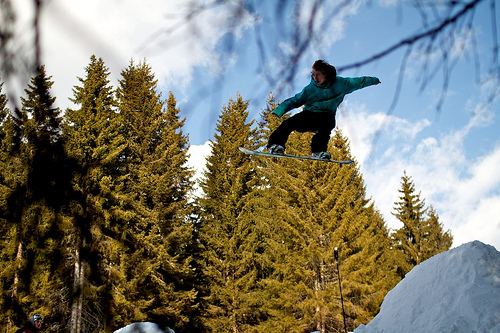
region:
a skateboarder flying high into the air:
[13, 8, 463, 313]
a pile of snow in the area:
[335, 226, 495, 322]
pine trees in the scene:
[5, 40, 171, 325]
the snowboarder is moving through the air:
[267, 65, 383, 115]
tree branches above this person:
[192, 10, 472, 45]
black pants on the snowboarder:
[260, 120, 345, 145]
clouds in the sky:
[371, 115, 491, 210]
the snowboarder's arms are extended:
[265, 55, 395, 115]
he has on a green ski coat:
[260, 79, 371, 119]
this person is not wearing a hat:
[302, 58, 345, 89]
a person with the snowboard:
[228, 51, 388, 169]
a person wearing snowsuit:
[281, 67, 353, 162]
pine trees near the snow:
[221, 93, 383, 323]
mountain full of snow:
[417, 246, 499, 330]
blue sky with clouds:
[396, 102, 487, 192]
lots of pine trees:
[23, 70, 365, 302]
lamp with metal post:
[329, 243, 360, 329]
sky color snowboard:
[227, 137, 361, 171]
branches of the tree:
[393, 7, 487, 80]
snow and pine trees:
[21, 57, 200, 312]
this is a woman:
[284, 48, 399, 171]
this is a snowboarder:
[288, 111, 335, 173]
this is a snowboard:
[240, 146, 352, 180]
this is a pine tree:
[156, 169, 262, 285]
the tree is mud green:
[163, 175, 301, 315]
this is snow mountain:
[351, 253, 484, 324]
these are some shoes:
[250, 131, 380, 166]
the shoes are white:
[230, 133, 408, 223]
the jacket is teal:
[283, 93, 346, 119]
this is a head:
[285, 70, 320, 72]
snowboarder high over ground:
[235, 53, 385, 319]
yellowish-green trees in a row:
[6, 56, 443, 326]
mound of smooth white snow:
[355, 216, 492, 326]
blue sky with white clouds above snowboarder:
[1, 0, 491, 230]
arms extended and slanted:
[260, 70, 380, 115]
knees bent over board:
[235, 110, 345, 165]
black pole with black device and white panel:
[330, 240, 345, 330]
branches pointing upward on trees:
[165, 91, 410, 326]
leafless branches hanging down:
[140, 2, 495, 117]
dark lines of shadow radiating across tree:
[3, 107, 186, 323]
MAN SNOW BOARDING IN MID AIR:
[234, 54, 368, 144]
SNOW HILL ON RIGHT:
[331, 227, 491, 315]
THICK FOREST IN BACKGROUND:
[38, 191, 370, 325]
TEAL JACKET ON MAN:
[280, 81, 448, 138]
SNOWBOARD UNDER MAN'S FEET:
[238, 124, 369, 168]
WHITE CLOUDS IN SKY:
[361, 131, 462, 198]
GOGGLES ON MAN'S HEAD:
[304, 55, 352, 91]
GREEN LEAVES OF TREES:
[166, 191, 301, 246]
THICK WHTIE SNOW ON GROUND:
[439, 291, 491, 331]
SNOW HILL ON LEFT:
[114, 305, 183, 332]